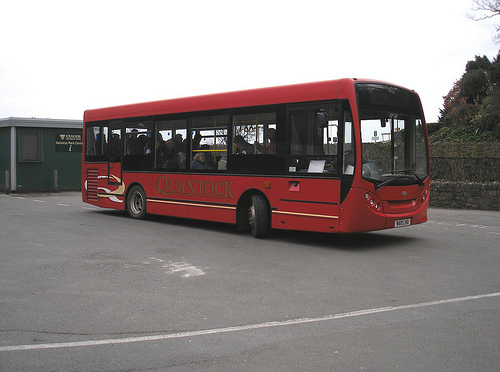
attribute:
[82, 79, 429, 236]
bus — red, black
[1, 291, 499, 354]
line — white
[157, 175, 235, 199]
letters — gold, black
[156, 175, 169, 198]
q — gold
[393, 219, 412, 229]
tag — white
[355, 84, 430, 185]
windshield — present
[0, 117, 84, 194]
building — green, white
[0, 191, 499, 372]
pavement — gray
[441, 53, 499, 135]
tree — bare, green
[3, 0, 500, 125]
sky — white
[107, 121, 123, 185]
door — present